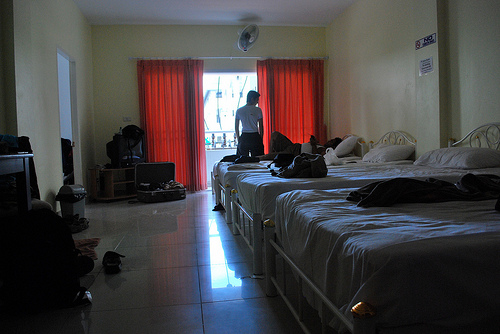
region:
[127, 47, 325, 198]
a couple red curtains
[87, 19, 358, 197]
a white wall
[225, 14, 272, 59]
a fan attached to the ceiling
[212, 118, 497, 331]
a couple of beds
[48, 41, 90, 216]
an entrance to the next room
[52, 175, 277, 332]
a tile floor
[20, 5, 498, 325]
a scene indoors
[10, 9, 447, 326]
a scene during the day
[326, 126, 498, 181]
three white peoples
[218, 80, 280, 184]
a person standing up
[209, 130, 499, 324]
four beds are in the room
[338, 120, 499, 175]
the head boards are white metal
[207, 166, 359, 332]
the bed footboards are matching metal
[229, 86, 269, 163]
a boy is standing by a bed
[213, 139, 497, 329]
the beds are queen size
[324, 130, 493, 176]
white pillows are onthe beds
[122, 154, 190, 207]
an open suitcase is on the floor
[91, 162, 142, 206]
a wooden shelf is in the corner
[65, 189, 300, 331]
the floor is white marble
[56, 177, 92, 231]
a trash can is in the room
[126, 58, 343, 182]
Curtain is red color.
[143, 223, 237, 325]
Floor is made of tiles.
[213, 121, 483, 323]
Four cots are in the room.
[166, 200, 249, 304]
Sunlight reflection is seen in floor.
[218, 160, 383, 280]
Bed spread is white color.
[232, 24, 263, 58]
Fan is fixed in the wall.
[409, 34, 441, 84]
Picture are fixed to the wall.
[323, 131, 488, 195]
Pillow is white color.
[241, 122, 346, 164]
One man is lying in cot.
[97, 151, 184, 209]
Side table is in the corner of the room.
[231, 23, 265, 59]
white and blue wall fan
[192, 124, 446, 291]
A room with three beds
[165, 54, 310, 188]
A large window with red curtains.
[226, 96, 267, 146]
A man facing the window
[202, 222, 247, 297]
Light reflected from the window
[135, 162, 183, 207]
A suitcase full of material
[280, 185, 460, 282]
A white bed spread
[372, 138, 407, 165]
A pillow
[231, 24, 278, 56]
A fan attached to the wall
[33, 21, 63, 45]
a yellow wall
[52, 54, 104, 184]
an entrance door.